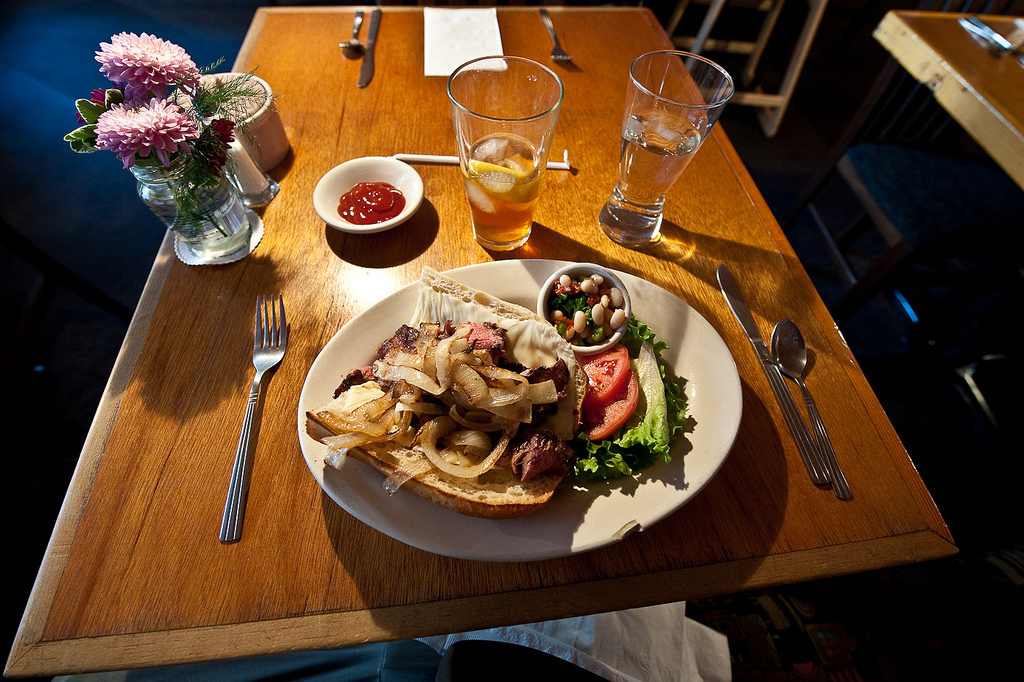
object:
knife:
[354, 4, 382, 90]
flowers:
[89, 30, 196, 96]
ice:
[483, 171, 515, 191]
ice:
[473, 137, 509, 160]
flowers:
[87, 107, 204, 169]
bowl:
[310, 151, 423, 232]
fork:
[207, 285, 291, 545]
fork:
[527, 7, 579, 66]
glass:
[600, 51, 737, 239]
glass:
[447, 51, 569, 257]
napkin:
[417, 4, 500, 80]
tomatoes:
[581, 349, 628, 403]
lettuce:
[575, 414, 667, 494]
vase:
[111, 153, 263, 268]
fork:
[206, 289, 286, 547]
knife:
[713, 261, 834, 488]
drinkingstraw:
[384, 140, 575, 173]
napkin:
[413, 599, 742, 680]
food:
[555, 271, 572, 290]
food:
[577, 343, 626, 397]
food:
[580, 363, 638, 437]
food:
[589, 302, 603, 319]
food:
[611, 302, 628, 323]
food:
[605, 283, 622, 309]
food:
[573, 311, 587, 328]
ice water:
[611, 107, 703, 222]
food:
[503, 432, 573, 485]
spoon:
[767, 312, 862, 503]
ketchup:
[335, 178, 406, 226]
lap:
[447, 602, 687, 680]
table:
[3, 3, 969, 678]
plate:
[289, 253, 750, 560]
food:
[380, 330, 478, 396]